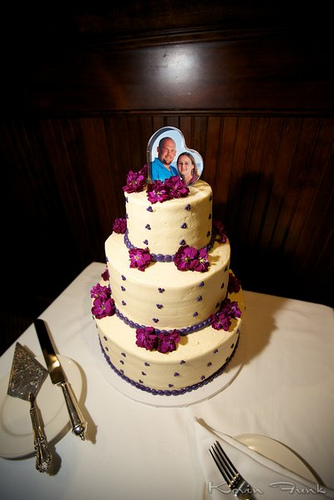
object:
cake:
[90, 125, 245, 397]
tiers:
[123, 183, 212, 263]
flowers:
[122, 167, 145, 195]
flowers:
[127, 247, 153, 273]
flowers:
[90, 296, 115, 321]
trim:
[121, 193, 141, 218]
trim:
[165, 288, 192, 325]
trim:
[165, 359, 187, 397]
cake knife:
[33, 315, 88, 448]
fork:
[207, 441, 260, 498]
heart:
[145, 124, 204, 186]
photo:
[152, 130, 203, 187]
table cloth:
[2, 256, 333, 497]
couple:
[152, 138, 200, 186]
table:
[0, 260, 334, 500]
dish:
[1, 351, 83, 460]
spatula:
[4, 337, 59, 475]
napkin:
[191, 413, 330, 499]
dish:
[197, 432, 322, 498]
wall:
[0, 0, 333, 362]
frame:
[139, 127, 210, 184]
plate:
[89, 322, 247, 409]